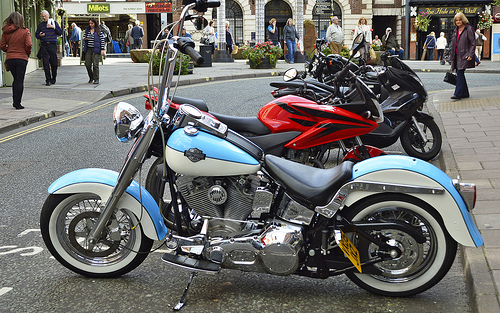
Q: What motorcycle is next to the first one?
A: A black and red motorcycle.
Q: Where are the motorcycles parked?
A: On the street.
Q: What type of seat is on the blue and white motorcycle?
A: A grey seat.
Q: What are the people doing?
A: Walking on the sidewalk.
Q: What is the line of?
A: Motorcycles.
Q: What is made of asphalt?
A: The ground.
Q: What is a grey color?
A: The ground.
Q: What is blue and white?
A: The bike.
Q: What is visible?
A: Motorcycles.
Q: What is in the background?
A: Buildings are in the background.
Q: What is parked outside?
A: The motorbikes are parked.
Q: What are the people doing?
A: The people are walking.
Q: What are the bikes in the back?
A: The bikes are black.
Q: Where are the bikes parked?
A: Motorbikes are parked at the sidewalk.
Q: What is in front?
A: A light blue and white motorcycle.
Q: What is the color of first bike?
A: Blue.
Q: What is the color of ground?
A: Grey.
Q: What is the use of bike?
A: Travel.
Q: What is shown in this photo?
A: Motorcycles.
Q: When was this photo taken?
A: During the day.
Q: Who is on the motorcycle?
A: No one.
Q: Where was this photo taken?
A: Outside on the street.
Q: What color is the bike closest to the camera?
A: Blue and white.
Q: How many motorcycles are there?
A: Four.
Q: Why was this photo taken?
A: To show the motorcycles.